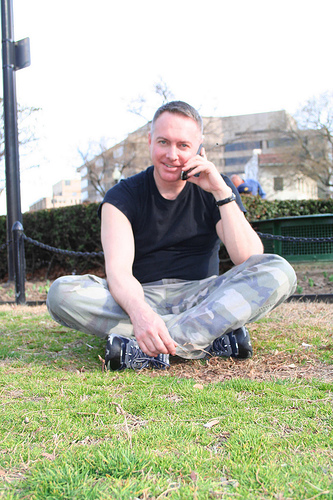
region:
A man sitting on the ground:
[44, 100, 294, 370]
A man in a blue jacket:
[231, 173, 263, 197]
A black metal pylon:
[9, 219, 29, 300]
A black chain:
[15, 231, 331, 256]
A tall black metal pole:
[1, 0, 29, 279]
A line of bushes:
[1, 199, 332, 273]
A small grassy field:
[0, 305, 332, 499]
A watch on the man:
[216, 191, 236, 205]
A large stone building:
[77, 110, 328, 205]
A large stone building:
[26, 178, 81, 210]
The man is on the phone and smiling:
[140, 98, 211, 190]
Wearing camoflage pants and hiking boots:
[101, 276, 270, 382]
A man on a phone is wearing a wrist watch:
[143, 99, 243, 224]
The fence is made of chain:
[8, 218, 73, 259]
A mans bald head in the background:
[234, 169, 267, 207]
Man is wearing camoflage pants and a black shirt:
[46, 116, 287, 376]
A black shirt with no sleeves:
[102, 168, 230, 282]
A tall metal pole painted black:
[0, 17, 30, 297]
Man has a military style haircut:
[139, 102, 214, 182]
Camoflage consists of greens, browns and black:
[189, 298, 254, 337]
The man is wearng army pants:
[49, 256, 296, 353]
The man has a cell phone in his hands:
[182, 147, 203, 177]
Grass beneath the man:
[1, 367, 331, 498]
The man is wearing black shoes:
[106, 327, 252, 366]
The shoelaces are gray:
[125, 346, 165, 367]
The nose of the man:
[166, 149, 178, 161]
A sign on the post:
[10, 37, 29, 71]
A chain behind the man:
[22, 230, 330, 256]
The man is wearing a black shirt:
[104, 166, 238, 282]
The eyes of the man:
[158, 138, 190, 147]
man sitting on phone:
[39, 88, 309, 371]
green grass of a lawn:
[128, 385, 304, 477]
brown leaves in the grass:
[192, 360, 295, 374]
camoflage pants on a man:
[185, 283, 275, 314]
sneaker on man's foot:
[217, 325, 251, 358]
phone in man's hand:
[174, 154, 205, 180]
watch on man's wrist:
[210, 191, 238, 203]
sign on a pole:
[0, 29, 38, 70]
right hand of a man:
[125, 318, 175, 354]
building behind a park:
[233, 98, 324, 199]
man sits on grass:
[35, 87, 307, 378]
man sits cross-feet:
[39, 93, 304, 395]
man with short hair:
[97, 90, 251, 229]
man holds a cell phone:
[90, 94, 255, 233]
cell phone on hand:
[175, 145, 223, 193]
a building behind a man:
[21, 93, 328, 228]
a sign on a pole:
[1, 0, 34, 308]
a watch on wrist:
[206, 181, 247, 217]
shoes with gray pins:
[90, 327, 260, 373]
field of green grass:
[5, 287, 331, 499]